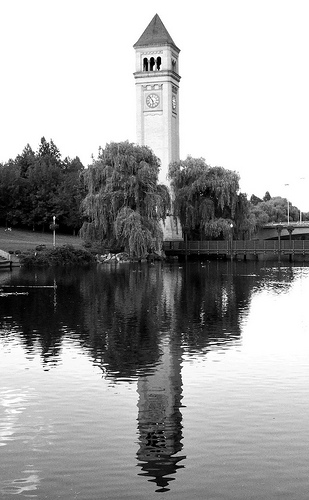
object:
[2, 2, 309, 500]
picture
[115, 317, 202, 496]
reflection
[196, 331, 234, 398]
water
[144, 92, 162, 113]
clock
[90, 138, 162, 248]
trees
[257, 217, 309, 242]
bridge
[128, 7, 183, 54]
roof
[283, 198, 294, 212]
lights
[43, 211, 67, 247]
light post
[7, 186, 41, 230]
shrubs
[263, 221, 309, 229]
freeway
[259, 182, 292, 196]
background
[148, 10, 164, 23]
tip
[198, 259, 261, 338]
tree shadows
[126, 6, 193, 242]
clock tower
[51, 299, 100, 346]
shadow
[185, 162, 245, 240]
tree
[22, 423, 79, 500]
pond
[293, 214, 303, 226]
driving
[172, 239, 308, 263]
bridge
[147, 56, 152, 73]
pillars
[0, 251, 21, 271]
fence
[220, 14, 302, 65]
sky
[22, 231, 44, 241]
grass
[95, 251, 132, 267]
rocks